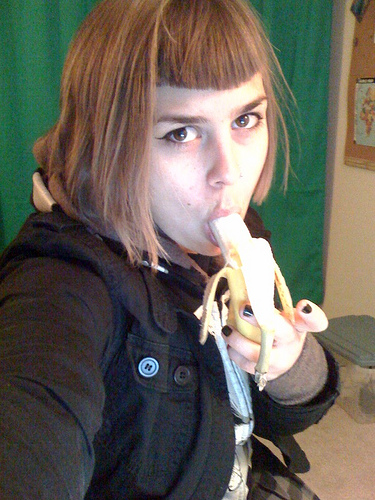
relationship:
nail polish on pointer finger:
[299, 303, 314, 314] [290, 298, 328, 332]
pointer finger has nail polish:
[290, 298, 328, 332] [299, 303, 314, 314]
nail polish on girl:
[299, 303, 314, 314] [0, 0, 343, 500]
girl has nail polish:
[0, 0, 343, 500] [299, 303, 314, 314]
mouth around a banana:
[205, 209, 247, 248] [195, 211, 301, 389]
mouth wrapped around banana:
[205, 208, 245, 249] [171, 196, 357, 393]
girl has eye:
[0, 0, 343, 500] [164, 125, 199, 142]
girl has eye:
[0, 0, 343, 500] [232, 112, 259, 129]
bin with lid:
[311, 314, 373, 424] [308, 315, 369, 363]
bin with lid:
[311, 313, 375, 425] [317, 312, 371, 367]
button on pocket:
[173, 363, 192, 387] [99, 334, 201, 494]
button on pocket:
[137, 353, 162, 380] [99, 334, 201, 494]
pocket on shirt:
[99, 334, 201, 494] [1, 166, 344, 497]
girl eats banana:
[0, 0, 343, 500] [196, 212, 331, 385]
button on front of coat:
[137, 353, 162, 380] [0, 206, 341, 499]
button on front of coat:
[174, 364, 191, 384] [0, 206, 341, 499]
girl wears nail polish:
[0, 0, 343, 500] [301, 303, 312, 313]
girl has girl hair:
[19, 1, 339, 494] [56, 0, 301, 278]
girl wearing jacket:
[0, 0, 343, 500] [33, 222, 300, 415]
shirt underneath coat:
[231, 364, 252, 494] [0, 205, 343, 500]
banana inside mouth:
[196, 212, 313, 393] [203, 206, 244, 245]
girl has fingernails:
[0, 0, 343, 500] [220, 300, 312, 337]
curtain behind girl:
[0, 0, 334, 309] [0, 0, 343, 500]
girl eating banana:
[0, 0, 343, 500] [200, 192, 321, 370]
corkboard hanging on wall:
[336, 34, 374, 173] [327, 18, 366, 288]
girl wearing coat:
[0, 0, 343, 500] [13, 248, 211, 495]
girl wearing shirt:
[0, 0, 343, 500] [230, 381, 257, 494]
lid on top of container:
[314, 313, 373, 371] [340, 362, 370, 419]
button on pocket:
[134, 351, 191, 385] [89, 333, 205, 473]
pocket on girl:
[89, 333, 205, 473] [0, 0, 343, 500]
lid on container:
[310, 313, 375, 371] [344, 369, 373, 410]